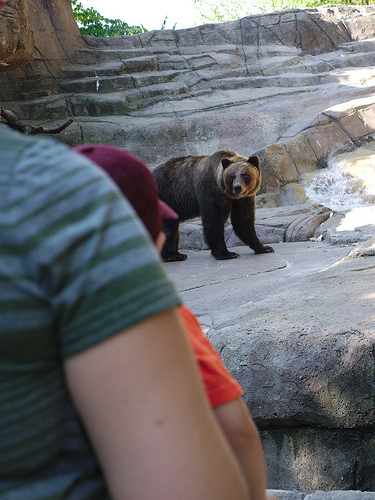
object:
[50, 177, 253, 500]
arm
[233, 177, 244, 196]
nose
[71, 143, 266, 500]
person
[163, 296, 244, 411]
orange shirt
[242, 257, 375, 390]
ground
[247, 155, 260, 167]
ear.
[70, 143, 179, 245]
cap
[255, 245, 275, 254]
paw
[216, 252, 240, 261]
paw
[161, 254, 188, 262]
paw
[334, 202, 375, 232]
light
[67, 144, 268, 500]
spot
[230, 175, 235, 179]
eyes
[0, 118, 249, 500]
person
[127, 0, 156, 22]
light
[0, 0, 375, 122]
exhibit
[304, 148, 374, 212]
water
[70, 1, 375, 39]
trees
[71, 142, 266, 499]
boy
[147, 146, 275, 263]
bear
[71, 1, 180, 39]
tree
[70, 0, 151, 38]
leaves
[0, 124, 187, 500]
tshirt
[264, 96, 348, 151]
rocks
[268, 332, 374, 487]
rock cliff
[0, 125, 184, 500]
shirt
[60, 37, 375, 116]
stick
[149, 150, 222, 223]
fur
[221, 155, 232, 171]
ear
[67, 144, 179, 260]
head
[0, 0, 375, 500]
zoo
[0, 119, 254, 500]
woman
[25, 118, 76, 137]
branch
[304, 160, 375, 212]
foam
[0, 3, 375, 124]
background